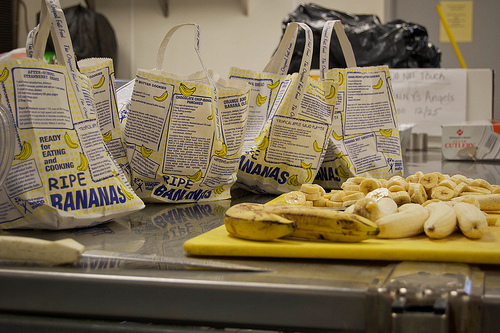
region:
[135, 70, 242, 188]
this is a bag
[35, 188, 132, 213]
this is a writing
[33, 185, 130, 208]
the writing is in blue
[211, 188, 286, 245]
this is a banana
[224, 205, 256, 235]
the banana is yellow in color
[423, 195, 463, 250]
this is a peeled banana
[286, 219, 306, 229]
this is the tip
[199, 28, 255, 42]
this is the wall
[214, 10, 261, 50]
the wall is white in color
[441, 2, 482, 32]
this is a notice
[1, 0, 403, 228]
row of bags with handles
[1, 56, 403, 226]
paper bags with blue text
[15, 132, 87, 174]
banana illustrations on bag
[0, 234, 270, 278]
knife with wood handle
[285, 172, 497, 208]
pile of sliced banana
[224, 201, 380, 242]
two bananas with black marks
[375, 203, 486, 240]
three peeled bananas in a row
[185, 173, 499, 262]
bananas on yellow cutting board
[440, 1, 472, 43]
yellow sign with text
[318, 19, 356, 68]
handle with blue writing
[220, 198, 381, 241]
Two bananas not peeled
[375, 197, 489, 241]
Three bananas that have been peeled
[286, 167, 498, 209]
Sliced bananas piled up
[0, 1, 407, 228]
Bags that say Ripe Bananas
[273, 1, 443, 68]
Black plastic garbage bag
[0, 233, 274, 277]
Cutting knife laying on its side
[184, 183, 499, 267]
Yellow plastic cutting board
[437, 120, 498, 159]
Box of plastic cutlery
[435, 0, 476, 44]
Yellow paper sign on a door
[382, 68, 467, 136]
White piece of paper with black writing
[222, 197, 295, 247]
A Banana on a cutting board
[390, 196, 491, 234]
peeled bananas on a cutting board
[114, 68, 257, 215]
a bag used to carry bananas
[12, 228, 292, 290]
a cutting knife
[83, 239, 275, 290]
the blade of a cutting knife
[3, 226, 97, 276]
the handle of a cutting knife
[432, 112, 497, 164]
a box containing cutlery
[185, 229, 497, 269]
a cutting board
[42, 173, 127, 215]
words that say Rip Bananas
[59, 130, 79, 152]
a picture of a banana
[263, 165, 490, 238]
these are banana on the tray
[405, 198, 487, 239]
the banana are pilled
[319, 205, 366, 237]
the banana is yellow in color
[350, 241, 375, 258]
this is the tray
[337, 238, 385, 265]
the tray is flat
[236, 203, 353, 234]
the banana are unpilled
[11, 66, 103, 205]
this is a sack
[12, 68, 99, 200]
the sack is white in color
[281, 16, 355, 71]
these are the handle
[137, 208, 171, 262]
this is the table